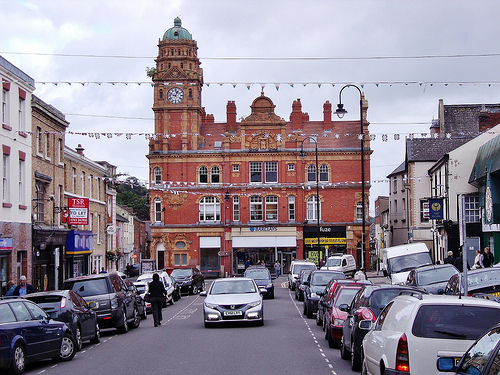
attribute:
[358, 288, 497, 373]
car — white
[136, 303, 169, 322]
trouser — part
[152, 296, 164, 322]
pants — dark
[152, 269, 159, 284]
hair — dark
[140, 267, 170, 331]
woman — walking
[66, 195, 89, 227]
sign — Red , white 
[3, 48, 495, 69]
power line — long, electrical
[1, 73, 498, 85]
power line — long, electrical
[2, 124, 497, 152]
power line — long, electrical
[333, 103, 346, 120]
lamp — off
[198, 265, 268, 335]
car — gray , small 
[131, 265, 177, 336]
lady — wearing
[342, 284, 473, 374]
car — blue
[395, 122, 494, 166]
rooftop — part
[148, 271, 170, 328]
woman — wearing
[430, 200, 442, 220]
sign — blue , yellow 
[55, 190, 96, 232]
banner — red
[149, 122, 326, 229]
building — red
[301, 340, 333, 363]
lines — white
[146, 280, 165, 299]
shirt — black